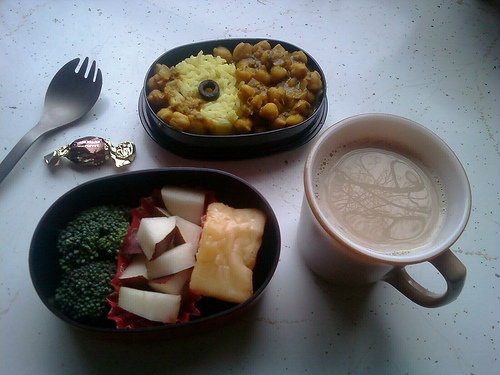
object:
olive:
[198, 79, 220, 98]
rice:
[179, 61, 215, 83]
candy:
[43, 135, 138, 169]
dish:
[137, 86, 328, 158]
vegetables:
[55, 261, 116, 310]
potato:
[162, 188, 202, 224]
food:
[55, 181, 266, 327]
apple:
[138, 220, 176, 256]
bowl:
[26, 168, 284, 335]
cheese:
[188, 201, 265, 303]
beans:
[267, 65, 285, 78]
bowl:
[141, 36, 326, 138]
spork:
[0, 58, 103, 186]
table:
[0, 0, 499, 375]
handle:
[386, 250, 466, 308]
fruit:
[117, 285, 183, 324]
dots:
[468, 97, 484, 114]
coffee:
[317, 144, 441, 248]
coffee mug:
[296, 111, 472, 309]